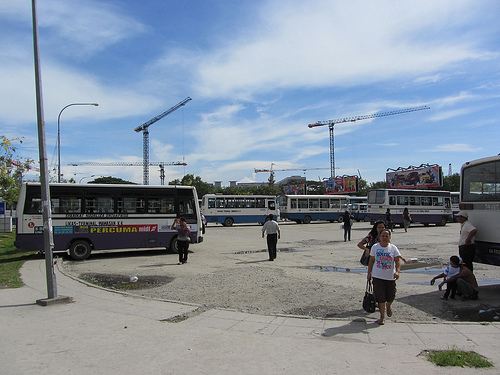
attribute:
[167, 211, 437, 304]
people — parking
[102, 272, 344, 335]
curb — curved , broken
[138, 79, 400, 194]
cranes — large, boom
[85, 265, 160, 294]
spot — dried up, of water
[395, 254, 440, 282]
water — a puddle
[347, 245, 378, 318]
purses — large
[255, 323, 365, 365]
sidewalk — grass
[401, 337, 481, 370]
patch — small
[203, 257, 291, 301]
lot — parking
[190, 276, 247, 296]
lot — parking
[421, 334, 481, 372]
patch — grass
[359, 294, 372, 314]
purse — black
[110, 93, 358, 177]
cranes — construction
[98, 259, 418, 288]
water — puddles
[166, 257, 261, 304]
lot — parking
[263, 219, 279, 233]
shirt — white 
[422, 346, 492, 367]
grass — square 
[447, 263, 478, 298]
boy — young 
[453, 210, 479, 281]
man — standing 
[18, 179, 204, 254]
bus — white and grey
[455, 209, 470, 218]
hat — white 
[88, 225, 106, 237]
letter — yellow 